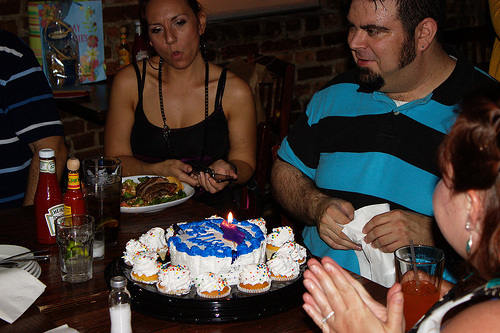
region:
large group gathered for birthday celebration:
[0, 3, 499, 324]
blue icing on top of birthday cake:
[131, 202, 317, 313]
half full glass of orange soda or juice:
[391, 235, 480, 331]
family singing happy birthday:
[0, 3, 490, 330]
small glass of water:
[37, 205, 128, 287]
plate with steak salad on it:
[98, 153, 221, 216]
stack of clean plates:
[1, 216, 47, 317]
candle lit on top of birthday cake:
[116, 212, 314, 317]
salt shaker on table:
[112, 273, 132, 331]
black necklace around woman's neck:
[126, 43, 253, 214]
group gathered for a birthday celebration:
[1, 3, 498, 330]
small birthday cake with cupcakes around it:
[123, 207, 310, 307]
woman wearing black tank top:
[97, 1, 253, 187]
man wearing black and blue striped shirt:
[265, 1, 498, 283]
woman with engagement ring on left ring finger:
[273, 61, 498, 331]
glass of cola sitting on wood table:
[72, 142, 133, 248]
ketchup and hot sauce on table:
[31, 145, 83, 255]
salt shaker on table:
[92, 272, 172, 330]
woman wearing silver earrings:
[275, 67, 497, 329]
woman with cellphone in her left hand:
[77, 0, 263, 200]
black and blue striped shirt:
[273, 61, 495, 290]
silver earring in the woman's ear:
[459, 215, 476, 255]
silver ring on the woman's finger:
[319, 308, 336, 329]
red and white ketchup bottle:
[30, 145, 63, 251]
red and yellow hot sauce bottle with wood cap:
[61, 155, 86, 237]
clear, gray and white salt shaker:
[105, 271, 134, 331]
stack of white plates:
[0, 239, 43, 286]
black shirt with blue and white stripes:
[1, 35, 64, 206]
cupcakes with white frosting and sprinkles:
[121, 213, 314, 299]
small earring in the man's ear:
[418, 39, 428, 52]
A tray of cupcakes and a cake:
[101, 204, 320, 324]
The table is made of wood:
[48, 281, 104, 326]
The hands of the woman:
[296, 255, 407, 330]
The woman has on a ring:
[317, 305, 341, 328]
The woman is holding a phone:
[176, 150, 232, 193]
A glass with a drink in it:
[77, 153, 131, 246]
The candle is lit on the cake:
[217, 208, 248, 250]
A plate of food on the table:
[102, 163, 197, 219]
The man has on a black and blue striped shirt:
[276, 72, 497, 290]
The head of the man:
[136, 0, 213, 76]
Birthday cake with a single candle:
[168, 208, 278, 267]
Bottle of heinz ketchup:
[25, 144, 65, 254]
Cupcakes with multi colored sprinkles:
[151, 261, 298, 304]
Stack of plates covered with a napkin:
[4, 236, 54, 330]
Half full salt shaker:
[101, 273, 147, 331]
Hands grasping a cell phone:
[172, 147, 246, 200]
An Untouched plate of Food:
[121, 164, 199, 225]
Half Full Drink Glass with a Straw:
[390, 236, 448, 331]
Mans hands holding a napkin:
[309, 186, 434, 266]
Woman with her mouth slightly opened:
[90, 3, 267, 158]